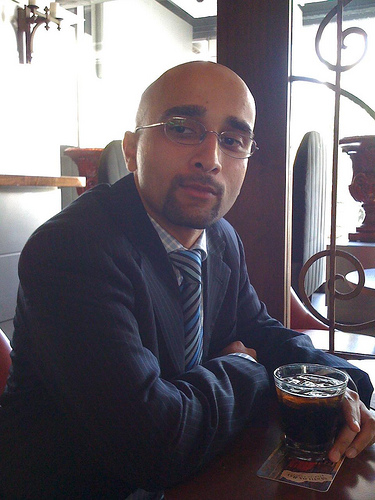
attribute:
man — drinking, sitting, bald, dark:
[106, 79, 308, 384]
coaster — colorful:
[267, 453, 324, 485]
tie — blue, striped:
[180, 271, 222, 339]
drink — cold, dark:
[265, 358, 374, 436]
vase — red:
[67, 145, 106, 184]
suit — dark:
[63, 210, 190, 339]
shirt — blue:
[163, 232, 176, 246]